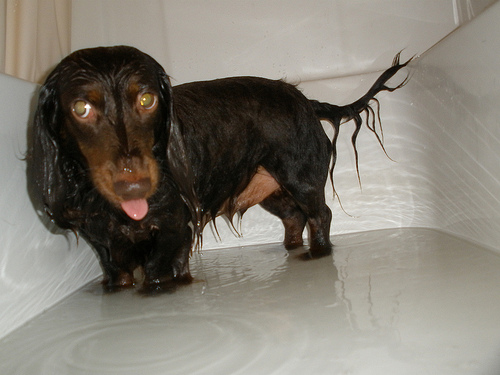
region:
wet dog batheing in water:
[29, 29, 433, 302]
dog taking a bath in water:
[19, 10, 424, 317]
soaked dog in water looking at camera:
[14, 18, 429, 300]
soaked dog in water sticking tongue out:
[25, 28, 462, 320]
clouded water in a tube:
[0, 221, 499, 371]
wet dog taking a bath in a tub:
[0, 3, 499, 374]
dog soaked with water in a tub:
[0, 13, 485, 345]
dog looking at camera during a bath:
[25, 22, 415, 295]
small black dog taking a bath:
[23, 45, 418, 296]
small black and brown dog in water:
[23, 38, 435, 298]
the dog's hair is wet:
[31, 52, 350, 299]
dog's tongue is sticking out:
[85, 159, 157, 242]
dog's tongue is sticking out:
[102, 164, 181, 248]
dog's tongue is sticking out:
[89, 175, 176, 255]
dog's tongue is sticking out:
[89, 154, 187, 245]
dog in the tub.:
[26, 33, 423, 296]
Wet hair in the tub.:
[20, 38, 425, 294]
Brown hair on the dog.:
[23, 40, 408, 295]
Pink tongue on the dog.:
[117, 194, 152, 225]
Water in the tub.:
[0, 220, 498, 372]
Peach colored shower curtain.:
[0, 1, 80, 91]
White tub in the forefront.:
[2, 3, 499, 372]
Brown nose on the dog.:
[108, 175, 155, 199]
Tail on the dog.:
[297, 53, 422, 139]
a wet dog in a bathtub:
[20, 45, 417, 297]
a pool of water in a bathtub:
[0, 225, 495, 371]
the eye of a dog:
[135, 90, 157, 110]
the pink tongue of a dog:
[115, 195, 147, 220]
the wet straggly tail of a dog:
[315, 52, 407, 207]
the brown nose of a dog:
[107, 171, 149, 192]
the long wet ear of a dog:
[25, 85, 90, 231]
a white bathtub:
[1, 1, 498, 374]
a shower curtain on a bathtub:
[0, 0, 78, 81]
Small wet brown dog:
[23, 40, 418, 297]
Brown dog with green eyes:
[17, 44, 415, 297]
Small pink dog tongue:
[121, 198, 149, 222]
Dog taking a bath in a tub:
[25, 38, 420, 296]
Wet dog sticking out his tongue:
[20, 38, 418, 298]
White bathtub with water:
[0, 0, 498, 372]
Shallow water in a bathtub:
[1, 221, 497, 373]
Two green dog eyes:
[67, 86, 158, 120]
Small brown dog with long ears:
[24, 46, 414, 295]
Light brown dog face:
[61, 65, 166, 224]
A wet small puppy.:
[13, 33, 424, 300]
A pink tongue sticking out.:
[113, 187, 153, 222]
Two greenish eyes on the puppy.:
[59, 80, 164, 124]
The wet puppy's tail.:
[301, 43, 418, 135]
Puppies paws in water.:
[53, 221, 410, 310]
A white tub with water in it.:
[5, 35, 493, 373]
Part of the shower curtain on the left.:
[0, 0, 88, 94]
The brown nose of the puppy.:
[104, 169, 159, 205]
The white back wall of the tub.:
[65, 1, 475, 96]